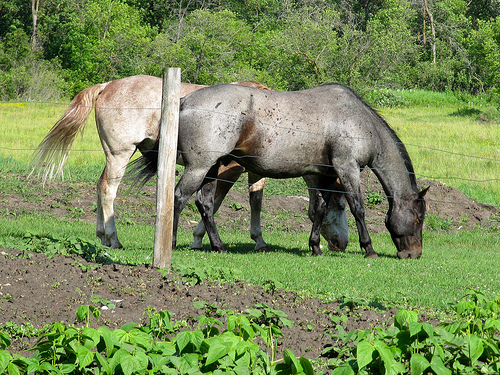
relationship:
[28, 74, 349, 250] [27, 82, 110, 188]
horse has tail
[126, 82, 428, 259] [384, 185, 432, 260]
horse has head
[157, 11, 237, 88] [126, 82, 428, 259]
tree behind horse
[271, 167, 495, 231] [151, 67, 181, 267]
dirt near post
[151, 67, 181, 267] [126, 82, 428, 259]
post near horse